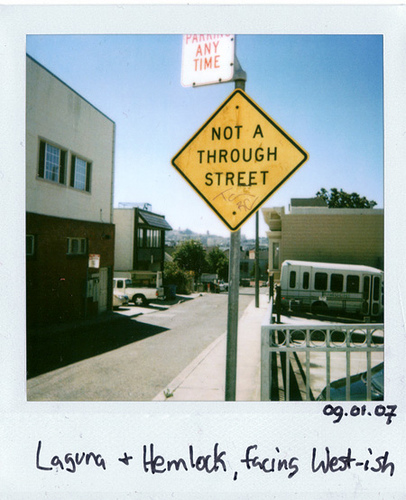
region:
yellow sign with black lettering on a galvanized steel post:
[170, 86, 310, 233]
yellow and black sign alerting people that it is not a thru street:
[167, 85, 307, 233]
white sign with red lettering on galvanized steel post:
[179, 33, 242, 84]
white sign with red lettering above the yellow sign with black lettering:
[174, 38, 236, 82]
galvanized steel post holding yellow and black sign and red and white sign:
[224, 240, 237, 396]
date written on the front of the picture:
[320, 403, 399, 430]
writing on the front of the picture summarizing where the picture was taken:
[30, 436, 395, 478]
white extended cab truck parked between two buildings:
[110, 274, 166, 308]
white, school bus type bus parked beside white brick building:
[275, 254, 382, 319]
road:
[114, 299, 191, 381]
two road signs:
[167, 33, 313, 245]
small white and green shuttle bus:
[277, 258, 382, 322]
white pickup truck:
[115, 274, 168, 307]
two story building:
[24, 51, 121, 341]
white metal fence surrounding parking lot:
[263, 296, 382, 402]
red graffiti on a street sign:
[209, 187, 258, 213]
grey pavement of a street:
[27, 294, 255, 403]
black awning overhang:
[133, 206, 173, 232]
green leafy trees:
[173, 242, 226, 273]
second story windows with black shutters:
[31, 126, 101, 202]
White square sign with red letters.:
[172, 33, 245, 87]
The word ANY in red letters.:
[185, 40, 229, 57]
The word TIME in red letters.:
[190, 54, 222, 73]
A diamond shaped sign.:
[165, 88, 309, 230]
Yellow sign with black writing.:
[168, 81, 314, 233]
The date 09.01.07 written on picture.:
[316, 400, 404, 424]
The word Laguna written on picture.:
[24, 432, 115, 473]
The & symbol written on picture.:
[118, 449, 136, 466]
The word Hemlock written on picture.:
[133, 436, 232, 479]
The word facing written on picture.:
[241, 434, 300, 482]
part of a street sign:
[181, 34, 241, 88]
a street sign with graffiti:
[169, 92, 302, 231]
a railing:
[257, 293, 390, 405]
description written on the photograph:
[34, 400, 398, 488]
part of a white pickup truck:
[113, 273, 175, 305]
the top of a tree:
[312, 188, 381, 214]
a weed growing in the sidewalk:
[160, 385, 181, 401]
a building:
[115, 204, 175, 305]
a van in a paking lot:
[276, 258, 383, 322]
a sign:
[86, 250, 104, 279]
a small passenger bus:
[266, 259, 387, 320]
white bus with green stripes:
[267, 256, 391, 325]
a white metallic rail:
[256, 317, 383, 401]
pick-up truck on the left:
[100, 269, 171, 309]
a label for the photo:
[33, 436, 398, 480]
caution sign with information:
[155, 88, 312, 234]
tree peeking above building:
[299, 182, 378, 217]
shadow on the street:
[28, 312, 174, 378]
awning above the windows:
[137, 211, 175, 231]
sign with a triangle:
[258, 203, 289, 234]